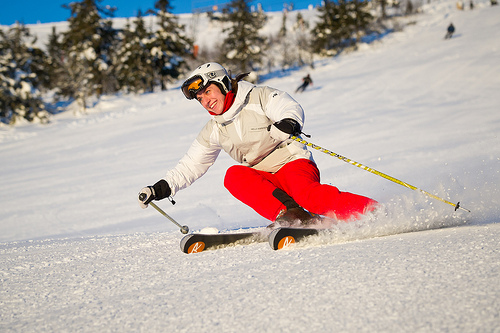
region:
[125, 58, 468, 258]
skier kicking up snow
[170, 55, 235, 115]
white helmet on skiers head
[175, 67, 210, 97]
goggles with yellow glass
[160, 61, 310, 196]
white winter coat on skier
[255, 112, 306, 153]
glove on skier's hand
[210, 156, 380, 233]
red pants on skier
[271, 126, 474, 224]
pole in skier's hand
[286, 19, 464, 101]
two skiers on the hill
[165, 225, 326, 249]
two skis with logo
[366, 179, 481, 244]
snow being kicked up by skier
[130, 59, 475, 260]
a happy woman skiing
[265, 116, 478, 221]
yellow ski pole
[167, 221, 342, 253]
black skis with golden stickers on the bottom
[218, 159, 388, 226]
red snow pants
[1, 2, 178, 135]
snowy coniferous trees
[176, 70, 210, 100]
ski goggles with an orange lens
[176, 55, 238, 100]
a white ski helmet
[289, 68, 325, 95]
a person skiing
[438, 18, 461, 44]
a person skiing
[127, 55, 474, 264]
a woman leaning to the side while skiing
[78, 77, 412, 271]
a skier in fluffy white snow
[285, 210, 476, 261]
snow flying from skis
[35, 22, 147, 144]
snowy trees in the background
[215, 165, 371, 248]
bright snow pants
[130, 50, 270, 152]
woman in white coat and helmet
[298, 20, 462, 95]
people going down the hill in the background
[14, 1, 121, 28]
bright blue skies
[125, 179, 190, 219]
black and white gloved hands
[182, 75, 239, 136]
smiling skiing lady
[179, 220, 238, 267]
orange emblems on black skis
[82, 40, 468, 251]
person out skiing in the snow.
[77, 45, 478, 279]
person enjoying a day of skiing.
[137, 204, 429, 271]
set of skies in the snow.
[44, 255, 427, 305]
white snow on a clear day.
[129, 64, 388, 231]
person wearing red pants during skiing.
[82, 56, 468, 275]
person wearing white jacket and red pants on ski trip.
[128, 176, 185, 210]
a dark glove in cold air.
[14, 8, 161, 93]
a cluster of trees out in the snow.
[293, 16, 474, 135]
people skiing down a snowy slope.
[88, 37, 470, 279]
a person skiing down a snow hill.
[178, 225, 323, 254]
The skis of the person nearest the camera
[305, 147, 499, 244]
The snow spraying behind the skier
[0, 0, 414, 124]
The trees in the background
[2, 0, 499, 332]
The snow on the ground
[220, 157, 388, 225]
The red pants the skier is wearing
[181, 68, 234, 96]
The goggles on top of the skier's head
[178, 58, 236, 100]
The white helmet on the skier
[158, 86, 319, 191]
The white coat of the skier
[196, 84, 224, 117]
The face of the skier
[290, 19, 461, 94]
The two skiers in the background